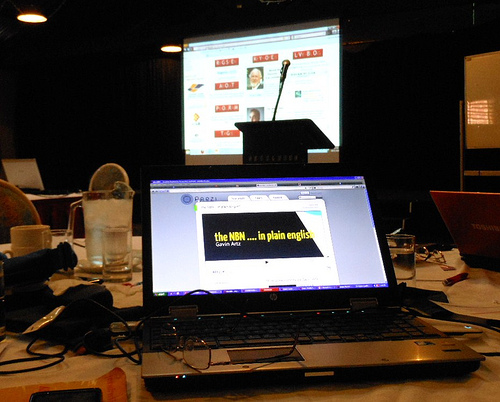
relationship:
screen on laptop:
[150, 176, 387, 291] [135, 158, 486, 390]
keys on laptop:
[150, 312, 430, 347] [135, 158, 486, 390]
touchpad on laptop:
[225, 343, 304, 364] [135, 158, 486, 390]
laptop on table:
[135, 158, 486, 390] [1, 233, 499, 401]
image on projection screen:
[246, 66, 263, 90] [178, 17, 345, 169]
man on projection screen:
[247, 108, 263, 122] [178, 17, 345, 169]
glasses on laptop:
[157, 320, 305, 370] [135, 158, 486, 390]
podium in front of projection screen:
[235, 117, 336, 162] [178, 17, 345, 169]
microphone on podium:
[277, 59, 293, 88] [235, 117, 336, 162]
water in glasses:
[391, 249, 415, 279] [416, 244, 449, 268]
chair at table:
[0, 180, 41, 241] [1, 233, 499, 401]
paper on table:
[418, 265, 499, 310] [1, 233, 499, 401]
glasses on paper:
[416, 244, 449, 268] [413, 250, 484, 282]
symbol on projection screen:
[212, 57, 242, 67] [178, 17, 345, 169]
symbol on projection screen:
[214, 80, 238, 91] [178, 17, 345, 169]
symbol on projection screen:
[211, 101, 240, 112] [178, 17, 345, 169]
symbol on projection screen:
[214, 128, 241, 138] [178, 17, 345, 169]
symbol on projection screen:
[251, 51, 280, 62] [178, 17, 345, 169]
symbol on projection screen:
[293, 47, 325, 61] [178, 17, 345, 169]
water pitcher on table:
[63, 182, 136, 268] [1, 233, 499, 401]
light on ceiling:
[17, 4, 50, 26] [2, 2, 472, 68]